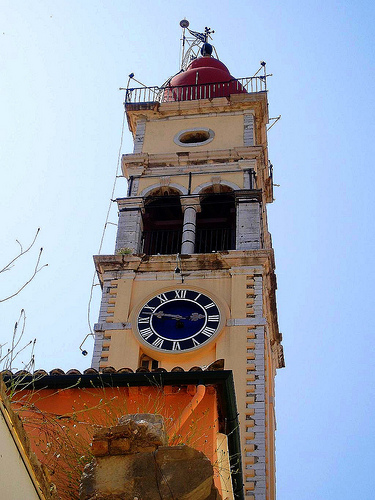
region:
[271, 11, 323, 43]
this is the sky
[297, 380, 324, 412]
the sky is blue in color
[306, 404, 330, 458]
the sky has clouds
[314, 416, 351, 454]
the clouds are white in color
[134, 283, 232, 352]
this is a clock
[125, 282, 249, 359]
the clock is big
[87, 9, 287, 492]
this is a building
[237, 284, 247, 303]
the wall is cream in color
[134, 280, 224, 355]
the clock is on the building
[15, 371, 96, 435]
these are some branches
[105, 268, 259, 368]
face of a clock in a tower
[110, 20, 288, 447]
a tall clock tower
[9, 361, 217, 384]
shingles on top of a roof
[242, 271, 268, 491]
interlaced brick work on a tower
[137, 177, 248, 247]
open arches in a tower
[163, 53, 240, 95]
red rounded dome top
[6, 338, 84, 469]
branches of a tree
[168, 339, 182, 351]
roman numeral six on a clock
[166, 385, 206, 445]
a drainage pipe coming down from a roof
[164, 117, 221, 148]
a window in a tower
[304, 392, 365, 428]
A blue tower background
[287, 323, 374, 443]
A blue sky tower background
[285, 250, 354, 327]
A blue sky tower background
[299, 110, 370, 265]
A blue sky tower background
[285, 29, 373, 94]
A blue sky tower background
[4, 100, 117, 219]
A blue sky tower background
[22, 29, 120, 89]
A blue sky tower background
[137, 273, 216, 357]
A blue tower watch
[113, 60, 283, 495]
A tall grey and cream tower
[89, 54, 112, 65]
this is the sky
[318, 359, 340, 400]
the sky is blue in color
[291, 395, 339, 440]
the sky has clouds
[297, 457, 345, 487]
the clouds are white in color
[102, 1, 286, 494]
the building is tall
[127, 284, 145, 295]
the wall is clean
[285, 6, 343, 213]
this is the sky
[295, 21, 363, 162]
the sky is blue in color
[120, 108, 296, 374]
this is a building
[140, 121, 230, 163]
this is the wall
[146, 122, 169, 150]
the wall is brown in color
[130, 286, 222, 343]
this is a clock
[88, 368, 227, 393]
this is the roof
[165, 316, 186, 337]
the clock is black in color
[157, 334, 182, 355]
this is a writing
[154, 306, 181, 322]
this is the minute